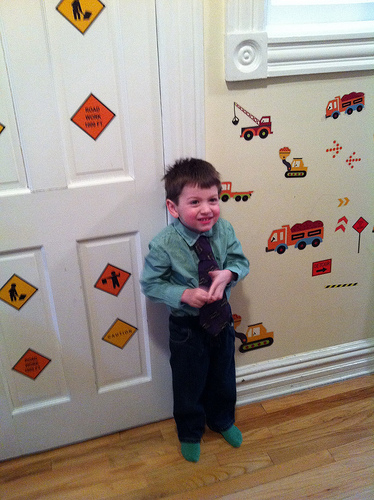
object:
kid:
[136, 153, 250, 467]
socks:
[178, 440, 203, 465]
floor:
[0, 369, 374, 499]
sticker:
[69, 91, 116, 144]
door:
[0, 0, 172, 465]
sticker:
[100, 316, 140, 351]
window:
[267, 0, 373, 36]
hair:
[160, 154, 225, 207]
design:
[232, 39, 262, 76]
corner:
[222, 30, 269, 87]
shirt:
[137, 221, 252, 318]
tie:
[192, 232, 234, 338]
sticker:
[265, 218, 323, 255]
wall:
[253, 91, 369, 336]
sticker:
[229, 101, 274, 143]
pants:
[166, 301, 238, 449]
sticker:
[92, 262, 133, 298]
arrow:
[326, 140, 344, 159]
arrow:
[345, 151, 361, 169]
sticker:
[278, 144, 309, 180]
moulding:
[221, 29, 374, 84]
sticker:
[219, 178, 255, 206]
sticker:
[350, 214, 369, 256]